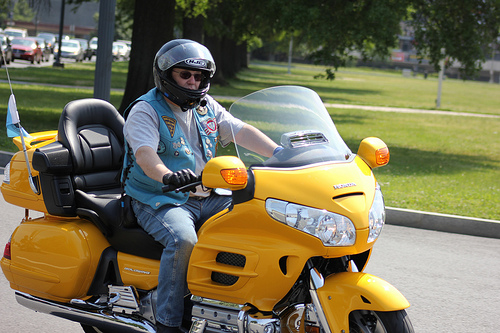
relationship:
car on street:
[11, 27, 48, 74] [3, 25, 93, 71]